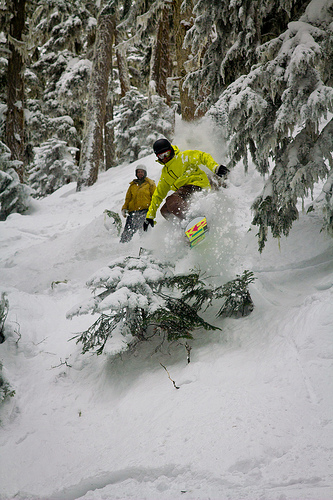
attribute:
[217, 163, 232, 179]
glove — black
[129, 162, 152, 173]
hat — white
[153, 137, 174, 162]
hat — black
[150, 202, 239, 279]
snow — in air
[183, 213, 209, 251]
snowboard — K2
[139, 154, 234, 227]
jacket — yellow, black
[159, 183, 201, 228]
pants — brown, snow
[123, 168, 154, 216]
man's jacket — yellowish, brown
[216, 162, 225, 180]
gloves — black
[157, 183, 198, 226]
pants — brown, man's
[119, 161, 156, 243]
man — standing, watching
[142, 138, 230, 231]
man — downhill